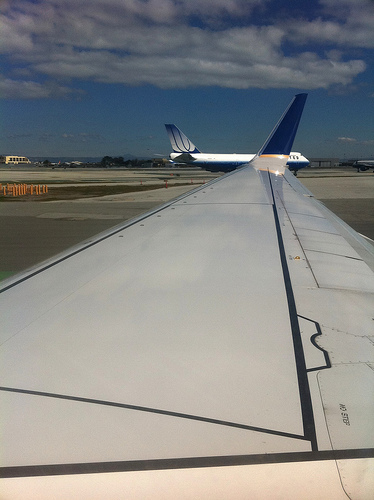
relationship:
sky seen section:
[0, 0, 370, 162] [91, 53, 192, 112]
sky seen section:
[0, 0, 370, 162] [1, 3, 71, 75]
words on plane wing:
[334, 399, 351, 426] [3, 93, 374, 493]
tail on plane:
[162, 118, 194, 154] [148, 86, 321, 165]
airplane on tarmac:
[152, 92, 324, 176] [2, 162, 372, 235]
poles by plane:
[3, 177, 51, 197] [155, 125, 313, 175]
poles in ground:
[3, 177, 51, 197] [4, 173, 144, 210]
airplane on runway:
[152, 94, 325, 175] [36, 167, 372, 186]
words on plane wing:
[334, 399, 351, 426] [3, 87, 372, 495]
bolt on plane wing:
[114, 233, 124, 240] [3, 93, 374, 493]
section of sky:
[132, 35, 228, 107] [0, 0, 370, 162]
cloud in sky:
[32, 44, 364, 89] [0, 0, 370, 162]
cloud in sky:
[10, 20, 295, 65] [0, 0, 370, 162]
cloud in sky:
[2, 2, 268, 27] [0, 0, 370, 162]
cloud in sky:
[311, 2, 369, 36] [0, 0, 370, 162]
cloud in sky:
[1, 71, 77, 100] [0, 0, 370, 162]